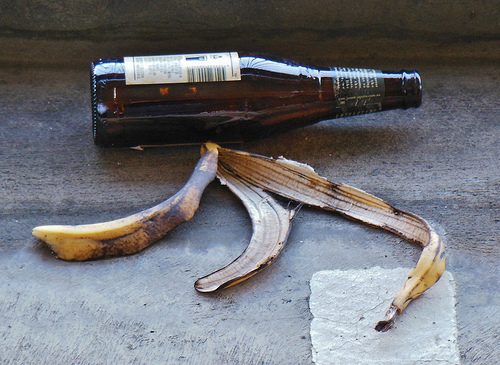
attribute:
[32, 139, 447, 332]
peel — banana, black, yellow, brown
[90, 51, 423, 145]
bottle — brown, glass, empty, beer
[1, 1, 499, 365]
floor — concrete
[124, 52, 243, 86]
label — white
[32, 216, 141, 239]
part — yellow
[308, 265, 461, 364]
patch — white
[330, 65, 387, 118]
label — green